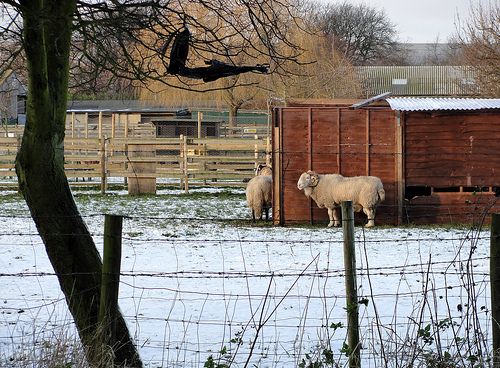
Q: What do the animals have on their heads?
A: Horns.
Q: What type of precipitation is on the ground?
A: Snow.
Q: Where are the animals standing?
A: Near the stable.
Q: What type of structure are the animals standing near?
A: A stable.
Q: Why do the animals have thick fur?
A: To keep warm.